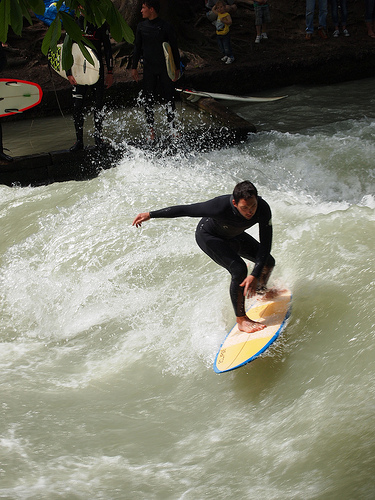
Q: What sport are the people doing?
A: Surfing.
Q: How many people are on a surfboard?
A: 1.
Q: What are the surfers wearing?
A: Wetsuits.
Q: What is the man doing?
A: Surfing.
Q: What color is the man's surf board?
A: Yellow and blue.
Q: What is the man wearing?
A: A wetsuit.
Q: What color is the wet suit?
A: Black.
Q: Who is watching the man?
A: Surfers.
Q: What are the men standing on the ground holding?
A: Surfboards.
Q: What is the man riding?
A: A wave.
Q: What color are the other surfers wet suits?
A: Black.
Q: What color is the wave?
A: White.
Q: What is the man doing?
A: Surfing.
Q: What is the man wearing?
A: A wetsuit.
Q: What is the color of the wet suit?
A: Black.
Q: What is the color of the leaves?
A: Green.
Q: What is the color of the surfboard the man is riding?
A: Blue and yellow.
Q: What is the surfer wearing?
A: A wetsuit.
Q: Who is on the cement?
A: More surfers.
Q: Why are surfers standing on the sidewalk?
A: Waiting their turn.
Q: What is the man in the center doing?
A: Surfing.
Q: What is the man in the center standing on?
A: A yellow surfboard.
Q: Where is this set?
A: In a city.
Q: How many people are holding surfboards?
A: Three.